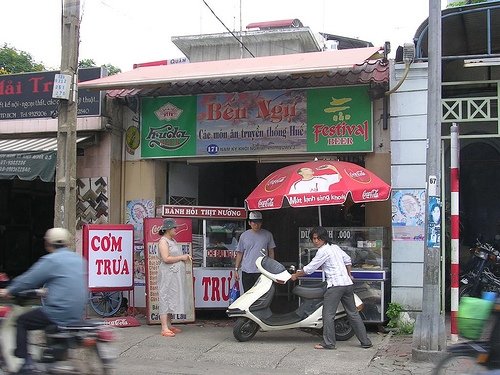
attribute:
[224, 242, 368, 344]
scooter — white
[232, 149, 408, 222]
umbrella — Coca cola, sun umbrella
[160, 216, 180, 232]
hat — gray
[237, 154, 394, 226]
umbrella — red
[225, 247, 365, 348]
scooter — gray, white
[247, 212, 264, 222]
hat — white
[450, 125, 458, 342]
pole — red, white, striped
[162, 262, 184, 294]
dress — long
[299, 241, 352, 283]
shirt — white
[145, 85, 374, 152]
sign — store's front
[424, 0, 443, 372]
pole — red, white